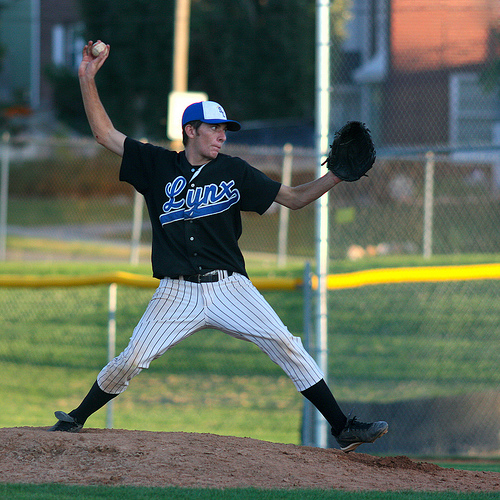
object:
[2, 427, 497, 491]
mound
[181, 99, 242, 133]
hat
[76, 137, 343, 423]
uniform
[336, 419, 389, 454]
shoe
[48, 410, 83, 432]
shoe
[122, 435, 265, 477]
dirt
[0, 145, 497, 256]
fence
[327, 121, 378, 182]
baseball glove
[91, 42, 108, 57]
baseball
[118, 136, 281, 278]
shirt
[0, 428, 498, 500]
baseball field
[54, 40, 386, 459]
baseball pitcher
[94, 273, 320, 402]
pants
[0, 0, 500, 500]
game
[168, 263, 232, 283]
belt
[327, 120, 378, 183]
hands